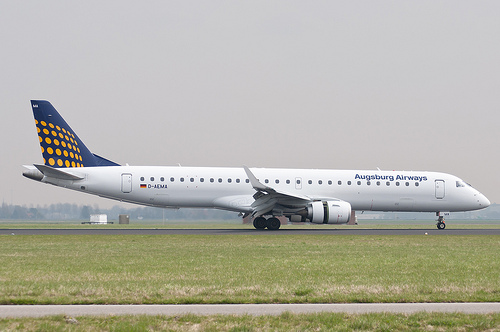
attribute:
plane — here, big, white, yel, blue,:
[19, 98, 491, 231]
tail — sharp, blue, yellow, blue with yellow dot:
[24, 99, 119, 187]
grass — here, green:
[3, 219, 499, 331]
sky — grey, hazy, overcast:
[1, 0, 496, 219]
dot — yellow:
[47, 155, 56, 168]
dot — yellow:
[44, 136, 53, 145]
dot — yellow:
[64, 160, 71, 166]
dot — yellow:
[53, 139, 62, 145]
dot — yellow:
[71, 144, 78, 151]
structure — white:
[87, 213, 110, 225]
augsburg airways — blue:
[353, 174, 428, 180]